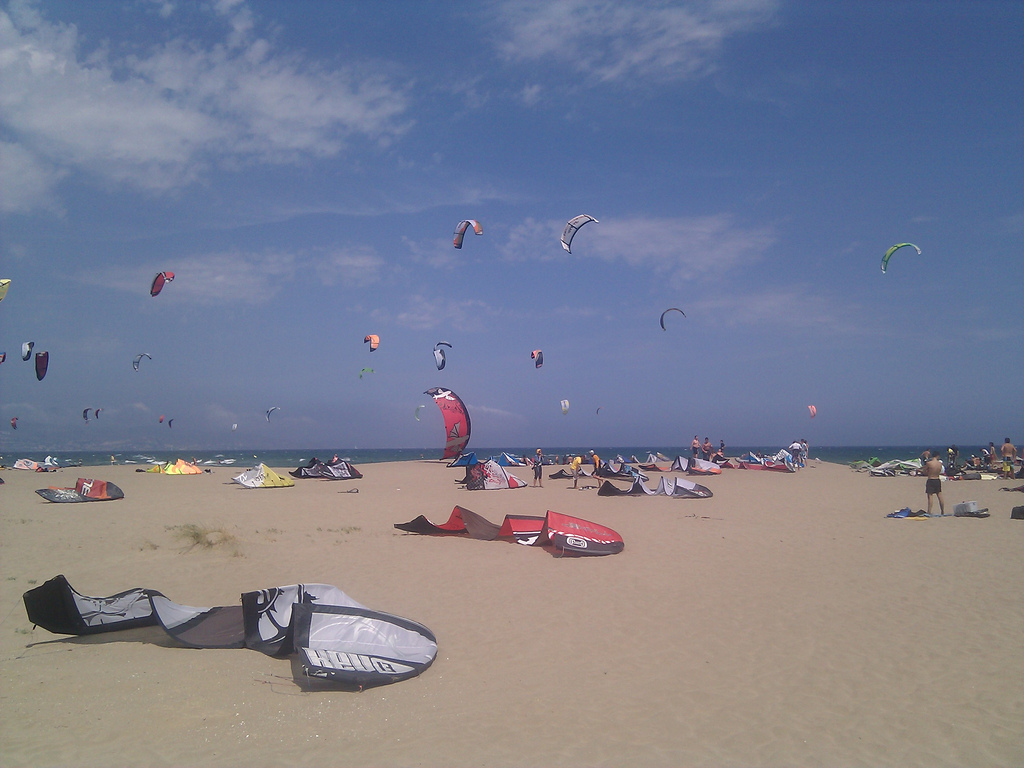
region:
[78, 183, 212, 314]
large colorful kites in sky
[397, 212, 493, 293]
large colorful kites in sky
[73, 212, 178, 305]
large colorful kites in sky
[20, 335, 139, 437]
large colorful kites in sky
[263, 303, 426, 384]
large colorful kites in sky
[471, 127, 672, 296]
large colorful kites in sky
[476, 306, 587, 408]
large colorful kites in sky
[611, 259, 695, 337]
large colorful kites in sky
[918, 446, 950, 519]
Man in black shorts.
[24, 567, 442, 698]
Black and white kite.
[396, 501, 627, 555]
red and black kite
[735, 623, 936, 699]
beige sand on beach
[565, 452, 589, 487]
person in yellow shirt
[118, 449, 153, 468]
waves of water splashing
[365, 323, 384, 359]
kite up in the sky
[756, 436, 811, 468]
people at kite event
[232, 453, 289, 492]
yellow and white kite on sand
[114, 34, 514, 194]
blue and white sky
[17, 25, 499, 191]
white clouds in sky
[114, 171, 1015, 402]
many kites in sky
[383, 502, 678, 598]
red and grey kite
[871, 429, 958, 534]
man stands on sand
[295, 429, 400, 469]
water is dark blue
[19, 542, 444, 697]
the black and white kite on the left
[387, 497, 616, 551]
the red and black kite on the sand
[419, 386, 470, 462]
the red and black kite standing straight up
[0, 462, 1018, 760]
the sand is brown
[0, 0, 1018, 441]
the sky has a few clouds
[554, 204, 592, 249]
the black and white kite in the sky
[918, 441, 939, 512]
the man in black shorts is standing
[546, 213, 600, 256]
a kite in the air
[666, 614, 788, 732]
the sand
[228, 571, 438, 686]
a white and grey kite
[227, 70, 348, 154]
clouds in the sky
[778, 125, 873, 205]
the sky is clear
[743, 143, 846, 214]
the sky is clear and blue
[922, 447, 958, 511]
a person standing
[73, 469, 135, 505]
a kite on the sand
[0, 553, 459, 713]
a white and black kite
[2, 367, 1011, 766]
people on a beach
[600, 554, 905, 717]
the sand on a beach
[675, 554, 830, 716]
the sand is tan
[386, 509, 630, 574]
a red and black and white kite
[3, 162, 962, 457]
kites in the sky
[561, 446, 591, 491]
a man wearing a yellow shirt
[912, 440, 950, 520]
a man wearing black shorts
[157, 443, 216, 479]
a yellow and white kite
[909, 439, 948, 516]
a man wearing no shirt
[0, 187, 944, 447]
Kites flying in the air.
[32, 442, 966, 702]
Kites on the ground.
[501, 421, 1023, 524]
People flying kites at the beach.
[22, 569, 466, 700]
A grey and black kite in the sand.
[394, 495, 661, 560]
A red and black kite in the sand.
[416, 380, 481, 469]
A large red and black kite just over the ground.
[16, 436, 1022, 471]
The ocean in the distance.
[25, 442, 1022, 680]
The sand has many kites on it.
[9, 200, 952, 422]
Colorful kites in the sky.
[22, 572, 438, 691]
the kite is black and white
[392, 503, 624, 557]
the kite is red, white and black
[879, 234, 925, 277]
the kite is green